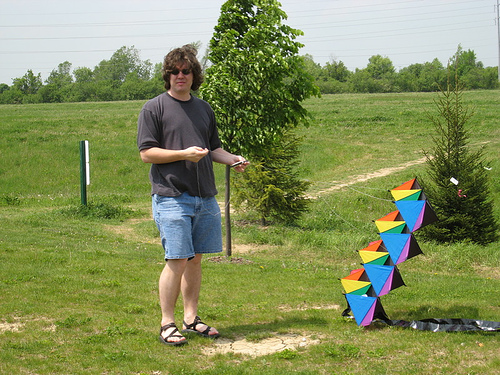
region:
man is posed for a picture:
[91, 49, 294, 311]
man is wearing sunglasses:
[102, 42, 252, 231]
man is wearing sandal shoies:
[148, 307, 230, 357]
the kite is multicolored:
[325, 189, 419, 304]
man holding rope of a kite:
[154, 52, 260, 313]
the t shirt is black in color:
[153, 114, 200, 166]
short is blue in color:
[148, 202, 235, 250]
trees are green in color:
[198, 4, 310, 188]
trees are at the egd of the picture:
[333, 46, 437, 86]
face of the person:
[158, 43, 235, 103]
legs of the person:
[139, 256, 224, 297]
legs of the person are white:
[148, 268, 254, 330]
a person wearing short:
[126, 165, 246, 266]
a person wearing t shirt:
[136, 101, 245, 188]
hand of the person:
[158, 140, 225, 167]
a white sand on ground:
[221, 320, 336, 368]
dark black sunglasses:
[167, 63, 193, 78]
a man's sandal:
[151, 321, 188, 346]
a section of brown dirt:
[215, 334, 308, 359]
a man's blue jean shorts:
[152, 190, 224, 257]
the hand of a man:
[182, 144, 211, 161]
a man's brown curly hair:
[160, 43, 204, 95]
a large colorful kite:
[317, 169, 496, 346]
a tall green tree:
[197, 0, 313, 232]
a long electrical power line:
[3, 11, 218, 31]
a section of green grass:
[21, 228, 110, 306]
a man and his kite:
[33, 29, 470, 365]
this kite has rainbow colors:
[292, 161, 452, 337]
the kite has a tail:
[394, 302, 497, 339]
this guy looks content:
[129, 42, 248, 362]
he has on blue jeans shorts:
[135, 174, 251, 265]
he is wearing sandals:
[149, 314, 233, 351]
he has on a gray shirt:
[122, 85, 243, 195]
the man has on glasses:
[146, 34, 218, 103]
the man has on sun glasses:
[164, 61, 200, 78]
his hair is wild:
[136, 45, 217, 94]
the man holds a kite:
[343, 177, 428, 333]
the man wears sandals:
[156, 319, 213, 342]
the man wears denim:
[156, 194, 218, 258]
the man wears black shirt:
[141, 95, 220, 193]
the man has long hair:
[160, 48, 204, 88]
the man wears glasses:
[166, 67, 191, 74]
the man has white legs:
[160, 253, 201, 328]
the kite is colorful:
[339, 177, 427, 324]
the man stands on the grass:
[136, 44, 244, 341]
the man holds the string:
[192, 148, 247, 211]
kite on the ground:
[310, 155, 447, 342]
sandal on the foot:
[154, 305, 189, 351]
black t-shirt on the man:
[126, 45, 249, 200]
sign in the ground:
[69, 131, 102, 204]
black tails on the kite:
[375, 304, 499, 341]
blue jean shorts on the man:
[128, 45, 253, 280]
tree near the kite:
[404, 64, 499, 246]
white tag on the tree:
[445, 170, 462, 188]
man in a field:
[132, 47, 252, 371]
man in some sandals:
[121, 25, 245, 357]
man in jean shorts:
[132, 29, 261, 354]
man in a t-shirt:
[126, 42, 266, 337]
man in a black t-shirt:
[138, 36, 250, 333]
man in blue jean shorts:
[131, 32, 238, 337]